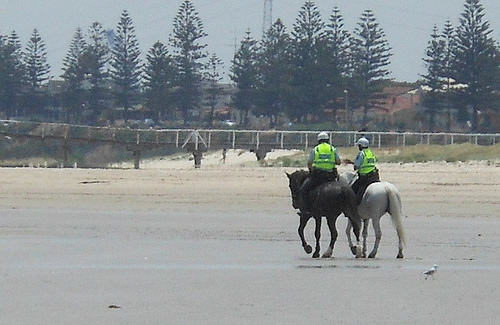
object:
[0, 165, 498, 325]
beach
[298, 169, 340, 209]
pants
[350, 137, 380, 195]
person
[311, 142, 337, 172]
vest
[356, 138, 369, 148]
helmet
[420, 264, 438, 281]
bird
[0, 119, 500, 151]
fence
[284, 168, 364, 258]
horse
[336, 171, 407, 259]
horse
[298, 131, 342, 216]
police officer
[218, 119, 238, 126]
car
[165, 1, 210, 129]
tree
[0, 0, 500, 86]
sky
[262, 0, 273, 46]
tower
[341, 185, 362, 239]
tail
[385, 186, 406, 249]
tail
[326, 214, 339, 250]
leg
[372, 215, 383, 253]
leg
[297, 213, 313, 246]
leg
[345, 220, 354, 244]
leg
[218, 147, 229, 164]
woman